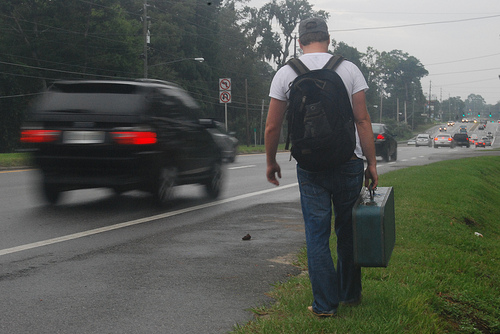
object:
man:
[264, 18, 379, 317]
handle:
[368, 184, 376, 200]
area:
[367, 169, 492, 333]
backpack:
[284, 54, 357, 171]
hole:
[463, 217, 476, 226]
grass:
[445, 276, 500, 311]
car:
[20, 76, 223, 210]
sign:
[219, 78, 232, 103]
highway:
[0, 159, 291, 263]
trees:
[237, 1, 330, 95]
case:
[351, 186, 396, 268]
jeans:
[297, 157, 365, 314]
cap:
[294, 18, 328, 38]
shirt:
[269, 52, 370, 164]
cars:
[433, 133, 454, 149]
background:
[355, 97, 499, 163]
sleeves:
[351, 63, 369, 95]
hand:
[364, 166, 378, 190]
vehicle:
[195, 118, 239, 163]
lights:
[109, 130, 157, 144]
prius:
[360, 122, 398, 162]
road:
[373, 135, 477, 164]